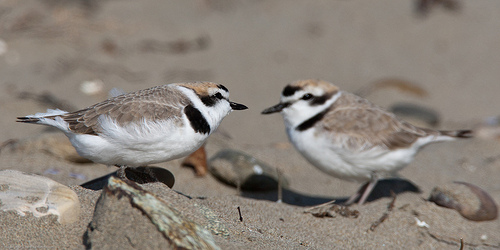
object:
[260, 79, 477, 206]
bird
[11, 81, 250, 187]
bird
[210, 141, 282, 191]
rock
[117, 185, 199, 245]
leaf